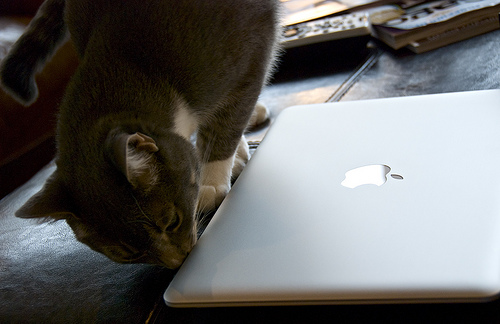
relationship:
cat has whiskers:
[2, 4, 280, 268] [188, 125, 225, 235]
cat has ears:
[2, 4, 280, 268] [14, 129, 160, 225]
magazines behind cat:
[276, 1, 496, 62] [2, 4, 280, 268]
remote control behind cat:
[278, 2, 385, 50] [2, 4, 280, 268]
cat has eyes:
[2, 4, 280, 268] [110, 207, 184, 264]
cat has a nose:
[2, 4, 280, 268] [160, 254, 185, 269]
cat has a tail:
[2, 4, 280, 268] [3, 0, 71, 106]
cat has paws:
[2, 4, 280, 268] [192, 117, 252, 212]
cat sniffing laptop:
[2, 4, 280, 268] [163, 88, 499, 303]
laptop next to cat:
[163, 88, 499, 303] [2, 4, 280, 268]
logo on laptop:
[338, 163, 404, 193] [163, 88, 499, 303]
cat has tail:
[2, 4, 280, 268] [3, 0, 71, 106]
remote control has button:
[278, 2, 385, 50] [284, 28, 299, 38]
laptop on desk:
[163, 88, 499, 303] [12, 85, 499, 321]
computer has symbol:
[163, 88, 499, 303] [338, 163, 404, 193]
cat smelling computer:
[2, 4, 280, 268] [163, 88, 499, 303]